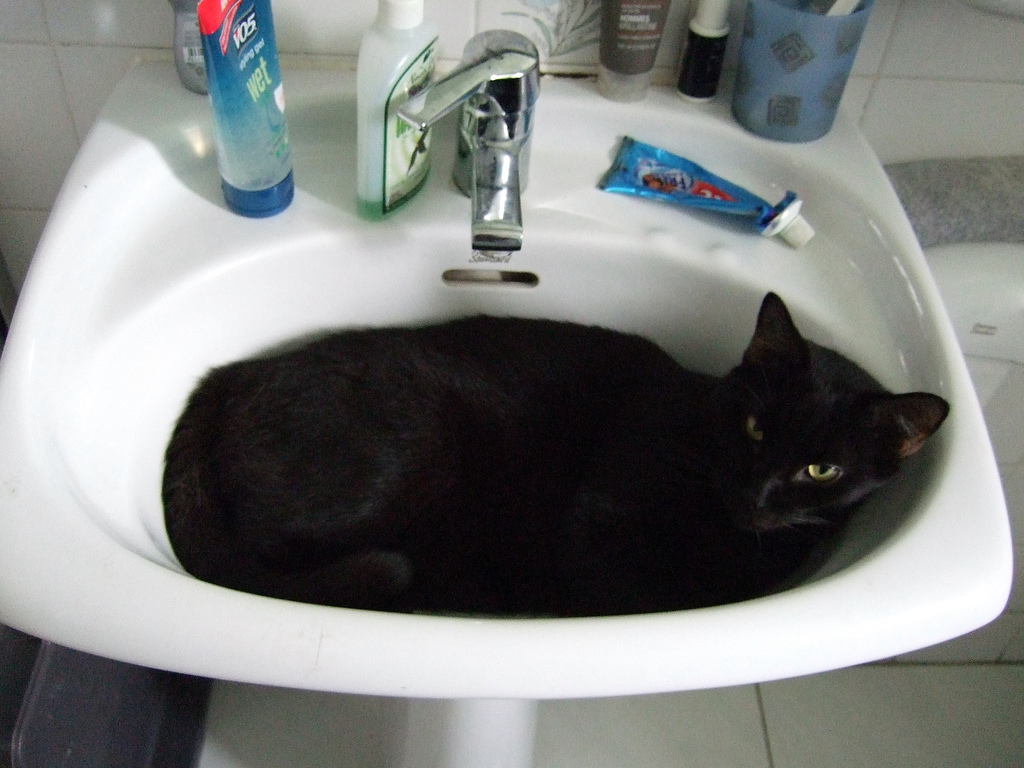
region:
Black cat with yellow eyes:
[163, 288, 954, 612]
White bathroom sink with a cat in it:
[2, 51, 1008, 704]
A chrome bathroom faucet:
[393, 45, 545, 265]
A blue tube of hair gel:
[174, 2, 327, 218]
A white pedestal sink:
[10, 47, 1017, 765]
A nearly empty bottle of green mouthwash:
[344, 2, 443, 222]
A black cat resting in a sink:
[152, 282, 947, 612]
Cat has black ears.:
[735, 274, 971, 446]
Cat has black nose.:
[738, 468, 792, 520]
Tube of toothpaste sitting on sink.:
[616, 121, 820, 251]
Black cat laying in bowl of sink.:
[160, 293, 926, 588]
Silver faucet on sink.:
[433, 21, 551, 284]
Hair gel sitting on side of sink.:
[209, 9, 289, 221]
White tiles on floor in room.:
[572, 705, 1000, 757]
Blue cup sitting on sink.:
[740, 4, 861, 157]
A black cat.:
[135, 265, 942, 630]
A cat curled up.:
[186, 300, 955, 630]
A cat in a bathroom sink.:
[107, 216, 973, 638]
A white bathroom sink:
[11, 32, 1021, 696]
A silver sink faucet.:
[413, 57, 538, 279]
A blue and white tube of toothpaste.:
[584, 121, 825, 251]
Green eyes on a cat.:
[736, 405, 860, 491]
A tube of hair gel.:
[195, 10, 301, 216]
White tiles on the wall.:
[6, 17, 1018, 252]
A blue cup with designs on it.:
[748, 7, 876, 143]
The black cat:
[175, 308, 897, 600]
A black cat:
[169, 305, 954, 623]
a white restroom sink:
[5, 4, 1011, 767]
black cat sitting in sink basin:
[0, 55, 1013, 698]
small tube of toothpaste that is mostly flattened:
[596, 132, 816, 250]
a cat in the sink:
[245, 252, 925, 704]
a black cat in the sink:
[288, 180, 665, 471]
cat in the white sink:
[418, 265, 834, 692]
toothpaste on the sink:
[666, 95, 793, 266]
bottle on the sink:
[178, 19, 340, 264]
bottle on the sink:
[352, 23, 438, 230]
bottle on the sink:
[564, 15, 640, 118]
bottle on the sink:
[681, 23, 735, 118]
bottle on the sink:
[160, 15, 233, 146]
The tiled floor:
[141, 669, 1023, 765]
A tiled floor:
[138, 644, 1023, 766]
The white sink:
[16, 211, 1022, 721]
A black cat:
[155, 277, 958, 633]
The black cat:
[147, 268, 963, 633]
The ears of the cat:
[738, 279, 958, 454]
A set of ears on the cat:
[742, 272, 981, 468]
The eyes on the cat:
[726, 401, 856, 490]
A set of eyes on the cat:
[714, 392, 873, 495]